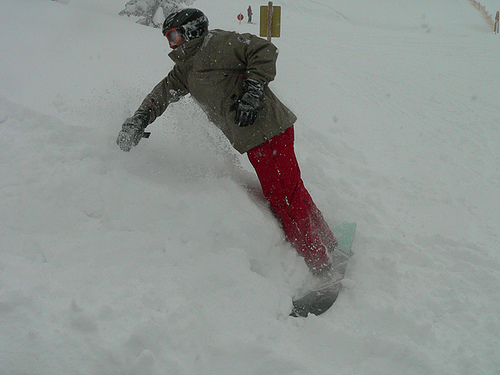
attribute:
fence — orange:
[467, 2, 495, 32]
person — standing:
[117, 9, 356, 321]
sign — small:
[238, 13, 244, 21]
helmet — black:
[162, 7, 209, 48]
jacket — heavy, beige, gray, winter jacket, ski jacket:
[124, 30, 298, 153]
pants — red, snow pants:
[247, 125, 340, 273]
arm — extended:
[119, 68, 188, 152]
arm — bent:
[234, 32, 277, 119]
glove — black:
[116, 112, 146, 152]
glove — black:
[230, 79, 269, 127]